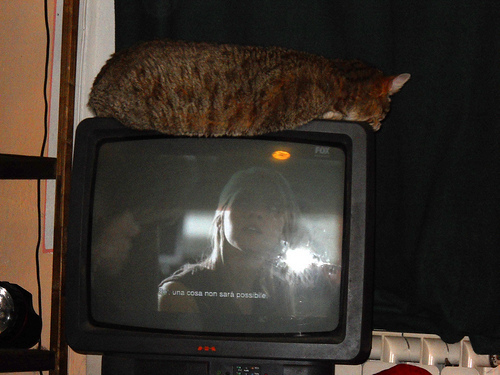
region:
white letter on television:
[311, 143, 323, 157]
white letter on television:
[317, 145, 327, 157]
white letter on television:
[261, 291, 268, 299]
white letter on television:
[251, 289, 260, 301]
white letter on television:
[246, 290, 253, 300]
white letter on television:
[242, 290, 251, 302]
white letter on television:
[171, 288, 179, 298]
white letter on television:
[174, 289, 184, 299]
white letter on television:
[178, 288, 185, 298]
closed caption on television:
[138, 276, 269, 306]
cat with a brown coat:
[89, 35, 414, 150]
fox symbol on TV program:
[310, 142, 344, 163]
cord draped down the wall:
[36, 5, 51, 305]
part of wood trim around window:
[50, 5, 81, 117]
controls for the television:
[231, 360, 263, 373]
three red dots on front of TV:
[187, 336, 222, 356]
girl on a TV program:
[157, 162, 318, 329]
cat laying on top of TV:
[60, 35, 413, 366]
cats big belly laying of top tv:
[108, 92, 318, 139]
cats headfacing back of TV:
[345, 56, 414, 128]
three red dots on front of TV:
[194, 343, 221, 352]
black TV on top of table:
[61, 114, 376, 362]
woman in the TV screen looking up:
[102, 144, 322, 331]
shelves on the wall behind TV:
[0, 0, 74, 372]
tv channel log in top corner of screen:
[306, 142, 338, 164]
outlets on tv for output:
[226, 361, 266, 373]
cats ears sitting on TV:
[387, 66, 412, 98]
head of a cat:
[331, 42, 422, 142]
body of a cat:
[75, 47, 340, 152]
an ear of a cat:
[388, 67, 420, 107]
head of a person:
[205, 167, 300, 258]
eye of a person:
[263, 200, 285, 218]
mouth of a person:
[237, 219, 268, 236]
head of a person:
[82, 164, 170, 274]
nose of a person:
[246, 207, 267, 218]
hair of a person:
[215, 162, 251, 199]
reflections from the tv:
[237, 147, 346, 296]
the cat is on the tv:
[63, 30, 419, 156]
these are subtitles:
[137, 268, 288, 315]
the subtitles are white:
[141, 278, 294, 313]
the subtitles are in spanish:
[136, 272, 296, 314]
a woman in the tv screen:
[148, 148, 334, 349]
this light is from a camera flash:
[264, 223, 354, 321]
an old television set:
[40, 80, 439, 371]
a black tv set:
[55, 98, 389, 372]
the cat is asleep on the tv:
[47, 18, 464, 156]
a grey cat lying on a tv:
[70, 15, 423, 155]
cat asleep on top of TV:
[75, 20, 417, 145]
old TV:
[76, 131, 351, 373]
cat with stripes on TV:
[51, 34, 421, 154]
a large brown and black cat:
[86, 32, 413, 134]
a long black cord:
[35, 0, 57, 361]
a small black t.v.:
[65, 110, 370, 362]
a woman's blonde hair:
[180, 164, 317, 270]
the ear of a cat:
[387, 68, 412, 93]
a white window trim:
[34, 0, 109, 251]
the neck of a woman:
[215, 235, 265, 298]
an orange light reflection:
[270, 147, 294, 160]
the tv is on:
[54, 30, 369, 347]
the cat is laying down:
[137, 30, 347, 92]